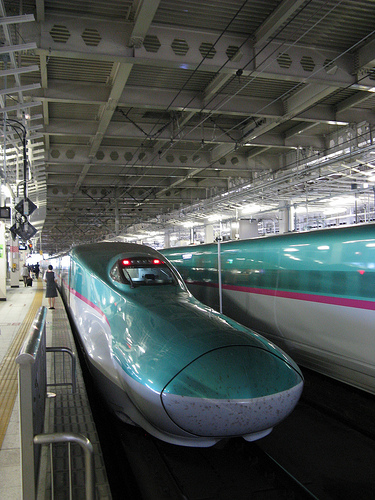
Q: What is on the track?
A: Train.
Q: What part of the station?
A: Roofing.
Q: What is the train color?
A: Green.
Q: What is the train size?
A: Large.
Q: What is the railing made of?
A: Metal.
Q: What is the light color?
A: Red.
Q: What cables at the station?
A: Electrical.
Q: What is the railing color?
A: Silver.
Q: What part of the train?
A: Front.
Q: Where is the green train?
A: At train station.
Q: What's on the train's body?
A: A red stripe.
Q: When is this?
A: Daytime.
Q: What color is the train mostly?
A: Teal.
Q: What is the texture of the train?
A: Smooth.